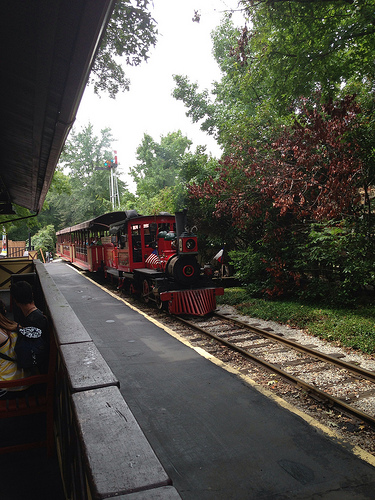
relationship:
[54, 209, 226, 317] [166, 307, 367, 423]
train on tracks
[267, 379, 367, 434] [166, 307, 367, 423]
leaves on tracks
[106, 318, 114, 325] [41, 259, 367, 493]
spot on platform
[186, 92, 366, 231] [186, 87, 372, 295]
leaves on tree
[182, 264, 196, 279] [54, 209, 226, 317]
circle on train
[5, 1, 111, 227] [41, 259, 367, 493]
hang above pavement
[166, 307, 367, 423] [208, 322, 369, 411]
tracks have gravel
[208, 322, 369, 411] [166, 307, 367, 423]
gravel in tracks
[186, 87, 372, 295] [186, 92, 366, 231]
tree has leaves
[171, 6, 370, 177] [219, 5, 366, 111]
tree has leaves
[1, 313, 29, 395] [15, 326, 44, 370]
person has backpack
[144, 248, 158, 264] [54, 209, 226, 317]
flag on train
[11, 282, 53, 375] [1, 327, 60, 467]
person on bench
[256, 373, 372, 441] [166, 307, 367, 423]
gravel around tracks